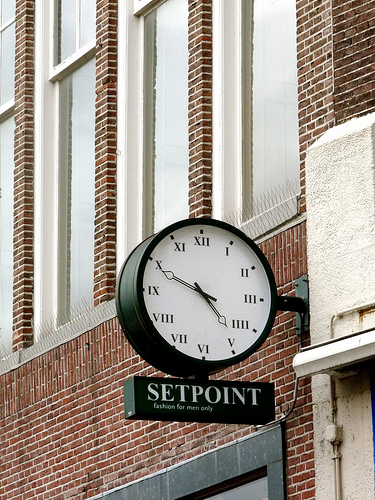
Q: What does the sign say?
A: SETPOINT.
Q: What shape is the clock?
A: Round.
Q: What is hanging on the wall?
A: Clock.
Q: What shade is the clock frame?
A: Black.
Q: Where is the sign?
A: Hanging under clock.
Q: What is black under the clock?
A: The sign.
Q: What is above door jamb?
A: Concrete.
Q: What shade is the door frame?
A: Black.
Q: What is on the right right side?
A: Area of brick wall clock is mounted on.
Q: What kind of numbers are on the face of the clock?
A: Roman numerals.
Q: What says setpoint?
A: The sign.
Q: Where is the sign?
A: Under the clock.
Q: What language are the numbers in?
A: Roman numerals.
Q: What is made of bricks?
A: The building.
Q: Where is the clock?
A: On the building.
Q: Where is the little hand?
A: On the five.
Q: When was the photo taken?
A: Daytime.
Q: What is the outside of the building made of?
A: Brick.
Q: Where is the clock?
A: Outside of building.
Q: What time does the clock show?
A: 4:49.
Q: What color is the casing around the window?
A: White.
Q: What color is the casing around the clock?
A: Black.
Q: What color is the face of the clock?
A: White.